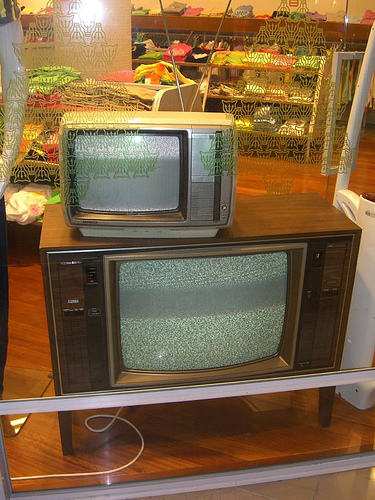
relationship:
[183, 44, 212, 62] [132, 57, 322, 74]
folded shirt on shelf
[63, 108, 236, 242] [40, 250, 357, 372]
tv on top of tv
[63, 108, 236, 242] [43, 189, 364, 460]
tv underneath television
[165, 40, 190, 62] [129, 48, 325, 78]
shirt on shelf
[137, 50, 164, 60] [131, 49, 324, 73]
shirt on shelf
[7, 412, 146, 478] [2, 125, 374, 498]
cord on top of ground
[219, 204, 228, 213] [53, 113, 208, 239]
button on tv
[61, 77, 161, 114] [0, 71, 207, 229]
clothes on shelf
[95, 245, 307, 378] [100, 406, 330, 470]
television sitting on floor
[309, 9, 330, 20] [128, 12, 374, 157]
shirt on shelf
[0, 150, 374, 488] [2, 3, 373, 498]
floor in store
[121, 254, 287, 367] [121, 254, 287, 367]
screen on screen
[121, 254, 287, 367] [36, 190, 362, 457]
screen of tv